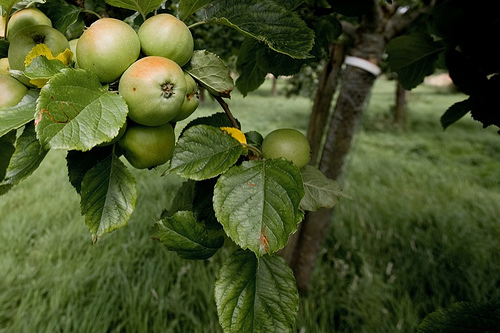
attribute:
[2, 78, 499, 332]
grass — green, short, ground, long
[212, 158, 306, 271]
leaf — green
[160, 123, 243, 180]
leaf — green, small, medium size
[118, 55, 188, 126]
fruit — green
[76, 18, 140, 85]
fruit — green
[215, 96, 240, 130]
branch — brown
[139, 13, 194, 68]
apple — ripe, green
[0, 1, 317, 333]
tree — young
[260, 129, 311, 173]
apple — fresh, green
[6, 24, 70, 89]
apple — green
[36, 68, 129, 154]
leaf — green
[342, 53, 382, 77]
band — white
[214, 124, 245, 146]
leaff — yellow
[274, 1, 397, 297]
trunk — brown